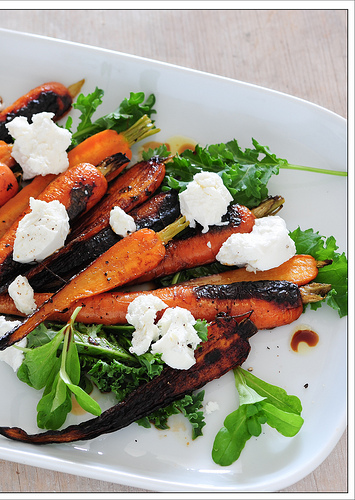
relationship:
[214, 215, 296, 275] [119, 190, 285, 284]
cheese on carrot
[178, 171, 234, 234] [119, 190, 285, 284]
cheese on carrot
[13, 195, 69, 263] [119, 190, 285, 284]
cheese on carrot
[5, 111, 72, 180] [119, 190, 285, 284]
cheese on carrot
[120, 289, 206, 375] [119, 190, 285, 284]
cheese on carrot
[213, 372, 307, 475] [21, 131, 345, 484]
herb on plate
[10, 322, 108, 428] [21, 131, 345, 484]
herb on plate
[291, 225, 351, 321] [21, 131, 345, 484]
herb on plate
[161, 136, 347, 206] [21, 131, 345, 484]
greens on plate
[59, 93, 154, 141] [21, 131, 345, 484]
herb on plate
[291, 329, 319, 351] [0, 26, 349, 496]
dressing on dish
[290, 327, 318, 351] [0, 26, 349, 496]
juice on dish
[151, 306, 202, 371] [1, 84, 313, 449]
cheese on carrot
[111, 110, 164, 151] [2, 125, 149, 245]
stem on carrots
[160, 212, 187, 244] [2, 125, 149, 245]
stem on carrots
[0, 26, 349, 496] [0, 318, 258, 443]
dish full of carrot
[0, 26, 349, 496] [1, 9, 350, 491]
dish on table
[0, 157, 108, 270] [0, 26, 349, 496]
carrot on dish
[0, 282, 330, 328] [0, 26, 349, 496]
carrot on dish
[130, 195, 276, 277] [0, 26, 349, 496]
carrot on dish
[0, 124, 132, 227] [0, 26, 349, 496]
carrot on dish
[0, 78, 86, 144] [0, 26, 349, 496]
carrot on dish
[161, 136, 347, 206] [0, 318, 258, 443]
greens under carrot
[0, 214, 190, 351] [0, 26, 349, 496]
carrot on dish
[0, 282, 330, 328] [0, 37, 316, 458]
carrot in dish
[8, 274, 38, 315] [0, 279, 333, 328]
cheese on carrot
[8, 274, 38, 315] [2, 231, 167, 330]
cheese on carrot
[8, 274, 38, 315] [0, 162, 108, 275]
cheese on carrot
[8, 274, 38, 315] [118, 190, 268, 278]
cheese on carrot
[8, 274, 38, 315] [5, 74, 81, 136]
cheese on carrot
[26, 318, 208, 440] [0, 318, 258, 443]
kale under carrot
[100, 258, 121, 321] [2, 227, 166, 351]
grains on carrot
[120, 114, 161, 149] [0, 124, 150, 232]
stem of carrot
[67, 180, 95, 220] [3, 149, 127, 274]
burn mark on carrot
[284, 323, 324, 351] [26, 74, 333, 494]
oil drop on plate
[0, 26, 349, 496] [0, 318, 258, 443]
dish on carrot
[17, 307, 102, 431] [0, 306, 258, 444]
herb under carrot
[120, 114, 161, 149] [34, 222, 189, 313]
stem of carrot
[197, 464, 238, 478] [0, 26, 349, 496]
reflection on dish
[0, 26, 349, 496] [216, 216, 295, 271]
dish with cheese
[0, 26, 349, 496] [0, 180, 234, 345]
dish with carrot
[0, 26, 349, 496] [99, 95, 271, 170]
dish contains greens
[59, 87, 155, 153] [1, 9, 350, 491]
herb on table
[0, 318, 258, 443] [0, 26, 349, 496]
carrot on dish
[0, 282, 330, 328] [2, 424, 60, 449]
carrot has tip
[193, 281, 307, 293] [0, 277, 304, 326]
burn mark on skin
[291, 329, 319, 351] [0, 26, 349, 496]
dressing spilled on dish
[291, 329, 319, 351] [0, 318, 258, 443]
dressing on carrot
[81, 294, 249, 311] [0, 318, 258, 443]
seasoning on carrot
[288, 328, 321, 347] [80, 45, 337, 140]
dressing on plate